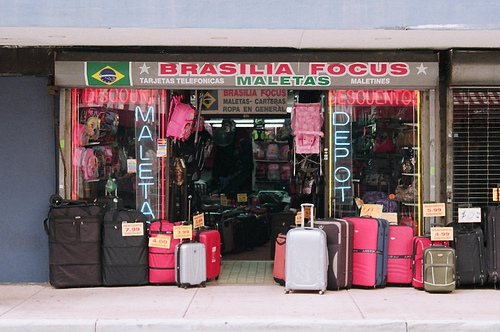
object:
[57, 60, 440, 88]
sign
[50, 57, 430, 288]
storefront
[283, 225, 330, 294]
luggage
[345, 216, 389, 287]
bag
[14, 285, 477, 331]
sidewalk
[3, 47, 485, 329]
store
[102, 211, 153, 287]
luggage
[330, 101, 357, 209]
sign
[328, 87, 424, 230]
window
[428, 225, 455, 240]
tag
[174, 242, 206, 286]
bag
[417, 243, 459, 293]
luggage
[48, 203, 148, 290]
bags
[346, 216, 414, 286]
bags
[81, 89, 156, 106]
sign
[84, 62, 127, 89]
flag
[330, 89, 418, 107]
lettering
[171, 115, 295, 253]
inside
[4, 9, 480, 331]
picture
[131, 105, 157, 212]
maleta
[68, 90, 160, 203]
window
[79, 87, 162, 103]
discount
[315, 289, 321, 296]
wheels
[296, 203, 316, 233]
handle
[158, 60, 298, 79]
brasilia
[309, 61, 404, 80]
focus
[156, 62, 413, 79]
writing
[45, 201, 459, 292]
suitcases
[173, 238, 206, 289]
suitcase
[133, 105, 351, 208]
signs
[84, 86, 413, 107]
signs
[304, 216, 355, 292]
suitcase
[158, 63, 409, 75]
lettering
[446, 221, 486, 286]
suitcase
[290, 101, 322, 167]
stroller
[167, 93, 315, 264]
doorway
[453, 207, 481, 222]
sign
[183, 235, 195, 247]
handle